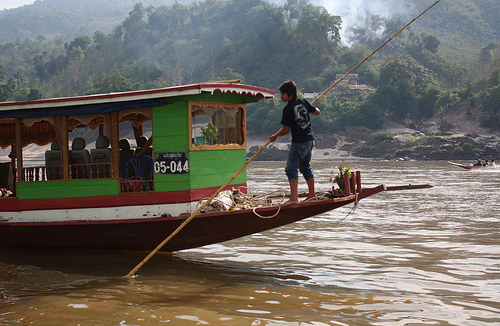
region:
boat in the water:
[2, 70, 437, 280]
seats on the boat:
[40, 132, 150, 174]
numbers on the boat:
[145, 146, 193, 178]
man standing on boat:
[269, 65, 324, 201]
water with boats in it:
[6, 160, 488, 322]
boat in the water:
[449, 155, 499, 172]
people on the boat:
[471, 160, 492, 169]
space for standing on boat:
[235, 172, 375, 214]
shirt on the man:
[281, 101, 316, 141]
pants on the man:
[275, 142, 315, 181]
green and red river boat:
[0, 81, 393, 261]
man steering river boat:
[257, 70, 327, 220]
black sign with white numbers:
[152, 152, 191, 174]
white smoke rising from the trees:
[273, 0, 405, 47]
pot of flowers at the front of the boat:
[328, 159, 358, 193]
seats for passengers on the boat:
[47, 135, 154, 177]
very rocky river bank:
[317, 130, 491, 155]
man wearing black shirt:
[269, 78, 327, 207]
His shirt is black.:
[277, 95, 319, 137]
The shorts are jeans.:
[270, 141, 334, 188]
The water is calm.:
[240, 166, 487, 324]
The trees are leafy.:
[20, 9, 498, 135]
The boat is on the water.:
[7, 81, 371, 236]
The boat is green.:
[0, 29, 445, 304]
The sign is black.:
[147, 143, 191, 183]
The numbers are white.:
[150, 150, 190, 175]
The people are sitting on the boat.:
[25, 100, 155, 187]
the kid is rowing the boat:
[96, 13, 383, 323]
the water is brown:
[69, 252, 456, 324]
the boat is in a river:
[4, 33, 495, 300]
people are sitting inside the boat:
[21, 95, 191, 197]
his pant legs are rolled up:
[278, 130, 333, 187]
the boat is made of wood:
[24, 58, 406, 307]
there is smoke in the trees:
[159, 0, 440, 94]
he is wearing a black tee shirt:
[260, 65, 360, 224]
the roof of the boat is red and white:
[1, 68, 277, 115]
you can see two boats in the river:
[2, 2, 497, 288]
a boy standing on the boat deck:
[274, 82, 319, 202]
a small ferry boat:
[0, 83, 383, 258]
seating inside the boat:
[44, 138, 111, 175]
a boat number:
[154, 153, 187, 175]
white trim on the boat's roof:
[197, 85, 273, 99]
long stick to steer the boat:
[125, 0, 438, 280]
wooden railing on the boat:
[18, 165, 116, 181]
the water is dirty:
[0, 160, 495, 323]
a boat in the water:
[447, 155, 495, 167]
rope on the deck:
[215, 187, 280, 221]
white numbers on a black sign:
[153, 150, 188, 171]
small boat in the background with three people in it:
[445, 155, 496, 167]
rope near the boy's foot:
[251, 189, 286, 219]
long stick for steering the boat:
[123, 0, 437, 276]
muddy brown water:
[0, 159, 499, 321]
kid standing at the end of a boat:
[268, 78, 319, 202]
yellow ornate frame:
[186, 100, 246, 150]